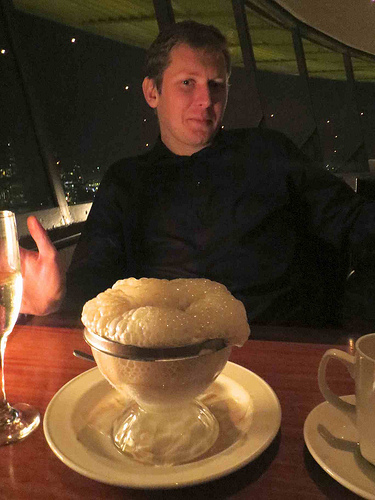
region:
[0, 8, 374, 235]
picture taken at night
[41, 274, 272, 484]
cup sitting on white plate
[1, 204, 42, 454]
half full glass on table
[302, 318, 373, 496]
cup sitting on white plate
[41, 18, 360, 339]
man wearing dark shirt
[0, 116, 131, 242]
city lights in the background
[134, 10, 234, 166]
man with dark hair and dark eyes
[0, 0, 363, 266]
place with scenic view of outside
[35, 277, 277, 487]
cup is half full of foam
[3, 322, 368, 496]
objects sitting on brown wooden table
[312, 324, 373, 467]
white coffee cup with handle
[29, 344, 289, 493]
white saucer on table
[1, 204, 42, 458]
wine glass with white wine inside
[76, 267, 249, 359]
some type of foam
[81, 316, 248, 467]
glass rammekin with food inside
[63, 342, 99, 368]
end of a spoon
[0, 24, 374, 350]
person wearing a black shirt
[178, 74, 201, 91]
eye of a person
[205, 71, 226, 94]
eye of a person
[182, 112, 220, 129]
mouth of a person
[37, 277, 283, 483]
cup om white plate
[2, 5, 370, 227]
scene taking place at night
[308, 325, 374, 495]
cup on white plate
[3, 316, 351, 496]
wooden brown table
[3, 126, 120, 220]
buildings seen in the background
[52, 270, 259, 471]
white foam in clear cup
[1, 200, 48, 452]
half filled glass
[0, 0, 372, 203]
scenic view of cityscape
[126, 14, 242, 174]
man has brown hair an brown eyes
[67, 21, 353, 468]
the window at the restaurant is round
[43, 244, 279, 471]
a foaming dessert in a bowl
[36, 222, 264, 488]
this is a dessert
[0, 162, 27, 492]
a glass of white wine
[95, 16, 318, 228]
the man wears black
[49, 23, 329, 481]
the end of the meal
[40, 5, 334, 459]
the table is wooden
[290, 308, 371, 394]
a coffee mug with dessert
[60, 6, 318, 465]
the rim of the bowl is silver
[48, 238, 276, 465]
the foam is spilling over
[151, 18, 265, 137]
face of the person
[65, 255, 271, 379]
an ice cube on plate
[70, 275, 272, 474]
a beautiful make up of food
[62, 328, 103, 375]
a part of the spoon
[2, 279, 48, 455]
a half portion of glass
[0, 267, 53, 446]
a glass with wine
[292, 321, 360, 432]
handle of the cup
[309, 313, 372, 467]
a coffee cup on plate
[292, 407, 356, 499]
a plate holding the cup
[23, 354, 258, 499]
a small plate holding food